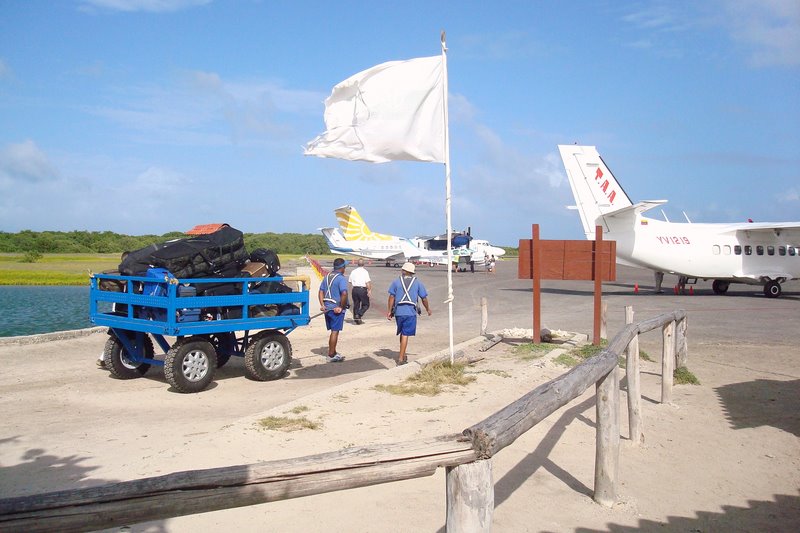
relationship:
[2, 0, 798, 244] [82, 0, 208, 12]
sky has cloud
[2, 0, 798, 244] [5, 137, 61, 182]
sky has cloud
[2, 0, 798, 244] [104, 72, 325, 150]
sky has cloud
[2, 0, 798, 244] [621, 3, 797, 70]
sky has cloud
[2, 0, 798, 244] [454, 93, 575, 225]
sky has cloud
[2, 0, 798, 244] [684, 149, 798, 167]
sky has cloud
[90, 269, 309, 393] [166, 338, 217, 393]
cart has back wheel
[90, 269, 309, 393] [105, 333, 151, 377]
cart has back wheel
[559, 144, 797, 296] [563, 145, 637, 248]
plane has a tail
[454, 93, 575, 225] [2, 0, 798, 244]
cloud in sky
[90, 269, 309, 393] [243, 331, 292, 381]
cart has wheel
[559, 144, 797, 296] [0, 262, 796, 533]
plane on top of floor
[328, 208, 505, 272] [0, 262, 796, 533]
plane on top of floor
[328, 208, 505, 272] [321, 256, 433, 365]
plane far from men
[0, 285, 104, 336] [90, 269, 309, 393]
pond near cart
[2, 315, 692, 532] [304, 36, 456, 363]
fence near flag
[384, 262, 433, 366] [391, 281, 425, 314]
man wearing shirt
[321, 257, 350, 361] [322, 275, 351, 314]
man wearing shirt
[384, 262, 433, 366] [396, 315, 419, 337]
man wearing shorts